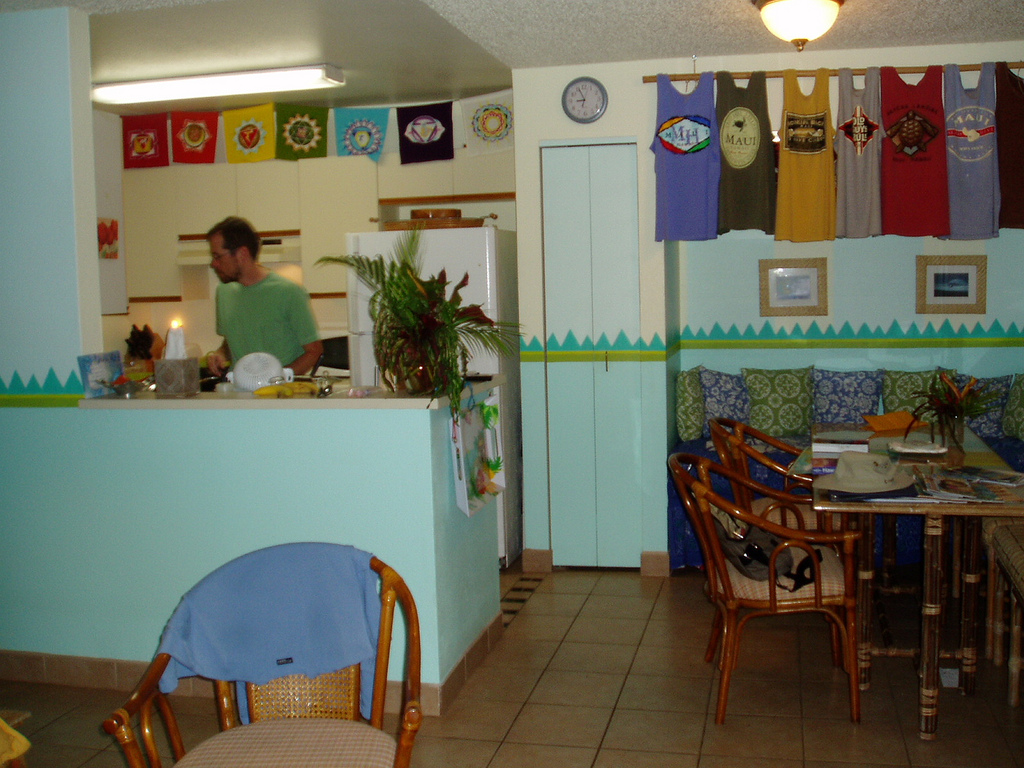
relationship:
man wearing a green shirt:
[198, 212, 322, 373] [206, 279, 323, 357]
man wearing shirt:
[198, 212, 322, 373] [205, 270, 316, 374]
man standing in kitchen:
[198, 211, 322, 372] [4, 0, 538, 714]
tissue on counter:
[153, 325, 199, 392] [0, 374, 508, 714]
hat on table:
[814, 448, 916, 494] [805, 420, 1019, 740]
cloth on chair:
[157, 543, 376, 719] [99, 538, 422, 763]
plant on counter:
[310, 219, 509, 418] [1, 369, 509, 415]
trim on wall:
[515, 315, 1023, 357] [515, 38, 1023, 576]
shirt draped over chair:
[143, 539, 383, 717] [99, 538, 422, 763]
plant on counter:
[310, 219, 509, 418] [0, 374, 508, 714]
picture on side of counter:
[450, 388, 509, 516] [0, 374, 508, 714]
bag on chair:
[712, 507, 825, 594] [666, 444, 867, 728]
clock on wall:
[556, 70, 615, 131] [515, 38, 1023, 576]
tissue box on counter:
[150, 323, 202, 401] [0, 374, 508, 714]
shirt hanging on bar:
[645, 70, 726, 245] [636, 57, 1023, 88]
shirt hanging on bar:
[712, 70, 780, 235] [636, 57, 1023, 88]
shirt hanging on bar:
[776, 66, 841, 242] [636, 57, 1023, 88]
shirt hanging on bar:
[830, 62, 883, 240] [636, 57, 1023, 88]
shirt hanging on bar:
[876, 64, 950, 240] [636, 57, 1023, 88]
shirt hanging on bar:
[938, 55, 1003, 244] [636, 57, 1023, 88]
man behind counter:
[198, 211, 322, 372] [0, 374, 508, 714]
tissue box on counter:
[150, 353, 202, 400] [0, 374, 508, 714]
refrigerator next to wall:
[344, 220, 522, 573] [515, 38, 1023, 576]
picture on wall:
[755, 252, 831, 322] [515, 38, 1023, 576]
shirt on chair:
[143, 539, 383, 717] [99, 538, 422, 763]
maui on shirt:
[656, 112, 719, 156] [645, 70, 726, 245]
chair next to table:
[666, 444, 867, 728] [805, 420, 1019, 740]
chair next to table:
[709, 414, 818, 490] [805, 420, 1019, 740]